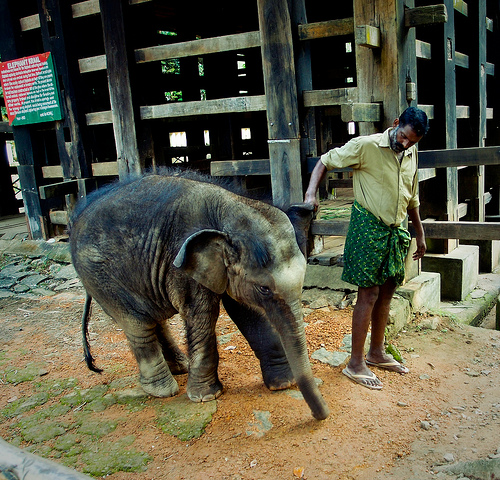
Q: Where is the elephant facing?
A: Right.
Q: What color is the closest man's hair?
A: Black.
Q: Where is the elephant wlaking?
A: In the dirt.